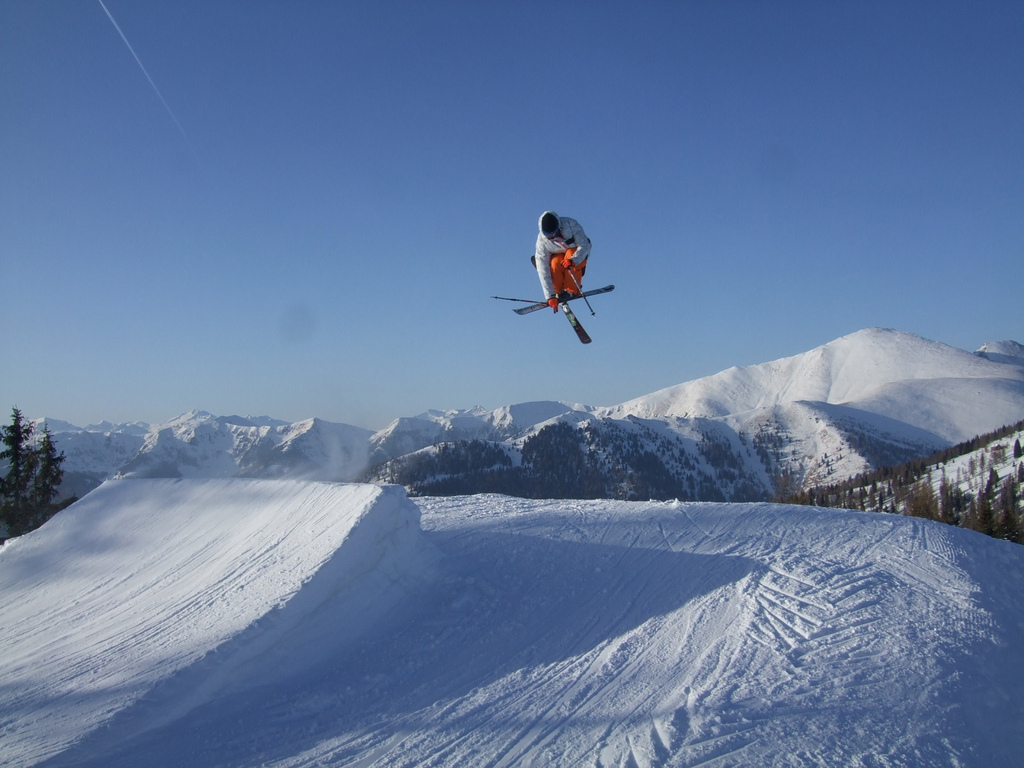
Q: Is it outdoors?
A: Yes, it is outdoors.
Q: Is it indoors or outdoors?
A: It is outdoors.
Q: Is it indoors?
A: No, it is outdoors.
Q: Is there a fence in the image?
A: No, there are no fences.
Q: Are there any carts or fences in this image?
A: No, there are no fences or carts.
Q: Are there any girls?
A: No, there are no girls.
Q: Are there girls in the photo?
A: No, there are no girls.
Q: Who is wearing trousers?
A: The man is wearing trousers.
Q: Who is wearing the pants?
A: The man is wearing trousers.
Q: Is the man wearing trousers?
A: Yes, the man is wearing trousers.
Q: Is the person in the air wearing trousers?
A: Yes, the man is wearing trousers.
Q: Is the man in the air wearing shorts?
A: No, the man is wearing trousers.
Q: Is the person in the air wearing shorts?
A: No, the man is wearing trousers.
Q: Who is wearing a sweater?
A: The man is wearing a sweater.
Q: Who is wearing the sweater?
A: The man is wearing a sweater.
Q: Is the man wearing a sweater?
A: Yes, the man is wearing a sweater.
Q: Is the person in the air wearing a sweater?
A: Yes, the man is wearing a sweater.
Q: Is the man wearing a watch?
A: No, the man is wearing a sweater.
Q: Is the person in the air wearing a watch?
A: No, the man is wearing a sweater.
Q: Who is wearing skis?
A: The man is wearing skis.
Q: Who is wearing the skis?
A: The man is wearing skis.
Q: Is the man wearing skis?
A: Yes, the man is wearing skis.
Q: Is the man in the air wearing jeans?
A: No, the man is wearing skis.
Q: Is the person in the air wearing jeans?
A: No, the man is wearing skis.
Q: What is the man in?
A: The man is in the air.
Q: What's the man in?
A: The man is in the air.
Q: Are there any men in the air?
A: Yes, there is a man in the air.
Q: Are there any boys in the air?
A: No, there is a man in the air.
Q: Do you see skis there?
A: Yes, there are skis.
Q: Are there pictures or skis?
A: Yes, there are skis.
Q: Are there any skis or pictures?
A: Yes, there are skis.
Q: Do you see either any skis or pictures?
A: Yes, there are skis.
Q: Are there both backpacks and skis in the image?
A: No, there are skis but no backpacks.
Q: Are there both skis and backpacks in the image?
A: No, there are skis but no backpacks.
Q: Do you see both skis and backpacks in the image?
A: No, there are skis but no backpacks.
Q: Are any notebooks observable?
A: No, there are no notebooks.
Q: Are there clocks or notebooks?
A: No, there are no notebooks or clocks.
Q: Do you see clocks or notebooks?
A: No, there are no notebooks or clocks.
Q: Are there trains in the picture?
A: No, there are no trains.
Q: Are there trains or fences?
A: No, there are no trains or fences.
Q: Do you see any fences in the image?
A: No, there are no fences.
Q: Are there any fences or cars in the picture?
A: No, there are no fences or cars.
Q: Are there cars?
A: No, there are no cars.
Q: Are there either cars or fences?
A: No, there are no cars or fences.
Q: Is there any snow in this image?
A: Yes, there is snow.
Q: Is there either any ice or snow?
A: Yes, there is snow.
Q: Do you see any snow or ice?
A: Yes, there is snow.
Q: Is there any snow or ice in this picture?
A: Yes, there is snow.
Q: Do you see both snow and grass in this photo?
A: No, there is snow but no grass.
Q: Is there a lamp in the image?
A: No, there are no lamps.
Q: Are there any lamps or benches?
A: No, there are no lamps or benches.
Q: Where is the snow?
A: The snow is on the mountain.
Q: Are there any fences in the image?
A: No, there are no fences.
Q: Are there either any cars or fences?
A: No, there are no fences or cars.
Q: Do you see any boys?
A: No, there are no boys.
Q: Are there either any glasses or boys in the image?
A: No, there are no boys or glasses.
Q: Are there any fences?
A: No, there are no fences.